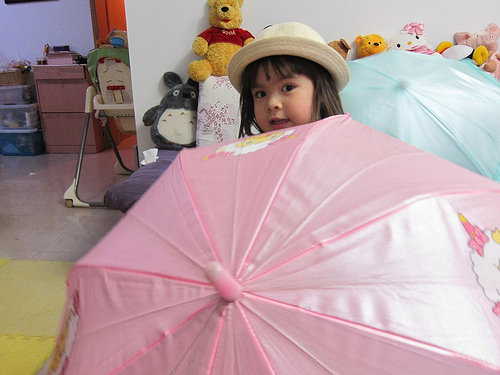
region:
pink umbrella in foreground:
[59, 117, 498, 374]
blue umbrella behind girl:
[339, 50, 499, 170]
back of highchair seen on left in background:
[69, 37, 141, 217]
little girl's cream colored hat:
[224, 22, 353, 90]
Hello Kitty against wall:
[384, 20, 441, 59]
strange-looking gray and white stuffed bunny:
[141, 70, 204, 160]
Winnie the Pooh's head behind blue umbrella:
[352, 32, 397, 60]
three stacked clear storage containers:
[0, 84, 40, 156]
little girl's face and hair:
[214, 60, 344, 135]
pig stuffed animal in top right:
[451, 24, 498, 54]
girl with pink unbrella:
[90, 118, 498, 374]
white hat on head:
[231, 19, 351, 80]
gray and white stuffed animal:
[137, 69, 201, 146]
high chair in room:
[86, 44, 128, 208]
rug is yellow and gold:
[0, 257, 62, 368]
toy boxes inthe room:
[0, 58, 45, 144]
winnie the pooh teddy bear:
[188, 3, 244, 78]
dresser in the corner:
[27, 64, 97, 156]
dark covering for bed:
[112, 146, 173, 214]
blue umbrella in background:
[364, 44, 496, 165]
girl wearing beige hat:
[209, 24, 365, 140]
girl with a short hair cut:
[217, 17, 342, 133]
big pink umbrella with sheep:
[62, 104, 464, 368]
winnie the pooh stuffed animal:
[194, 2, 256, 82]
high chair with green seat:
[64, 28, 157, 213]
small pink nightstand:
[27, 46, 103, 156]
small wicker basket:
[3, 61, 28, 84]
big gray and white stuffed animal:
[147, 65, 204, 149]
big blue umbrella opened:
[344, 45, 487, 166]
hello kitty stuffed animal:
[390, 19, 437, 77]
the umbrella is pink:
[236, 160, 386, 297]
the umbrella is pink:
[205, 164, 336, 258]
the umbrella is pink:
[246, 190, 330, 277]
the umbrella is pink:
[266, 195, 410, 309]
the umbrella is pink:
[282, 252, 386, 357]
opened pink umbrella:
[53, 114, 495, 373]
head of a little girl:
[225, 21, 346, 142]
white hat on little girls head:
[226, 21, 348, 90]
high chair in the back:
[71, 44, 136, 207]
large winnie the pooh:
[188, 0, 254, 80]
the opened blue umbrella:
[343, 51, 499, 167]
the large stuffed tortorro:
[143, 67, 200, 148]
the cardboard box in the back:
[33, 65, 105, 154]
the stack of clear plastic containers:
[1, 85, 40, 155]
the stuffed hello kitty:
[386, 21, 435, 57]